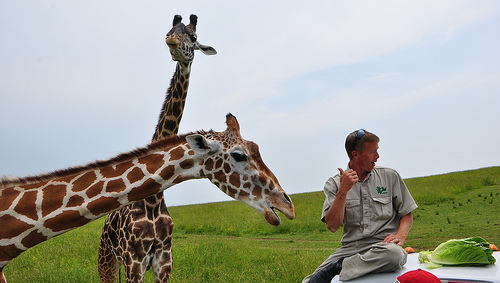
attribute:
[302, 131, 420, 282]
man — sitting down, pointing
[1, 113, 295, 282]
giraffe — looking down, large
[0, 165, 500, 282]
grass — green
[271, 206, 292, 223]
mouth — open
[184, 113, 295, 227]
head — bent down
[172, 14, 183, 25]
horn — tiny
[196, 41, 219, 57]
ear — sticking out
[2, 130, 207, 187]
hair — dark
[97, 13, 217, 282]
giraffe — tall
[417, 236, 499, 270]
leaves — large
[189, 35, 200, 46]
eye — small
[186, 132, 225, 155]
ear — white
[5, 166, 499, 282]
hill — small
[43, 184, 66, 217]
spot — brown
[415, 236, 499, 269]
lettuce piece — large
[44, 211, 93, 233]
spot — large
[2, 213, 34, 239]
spot — large